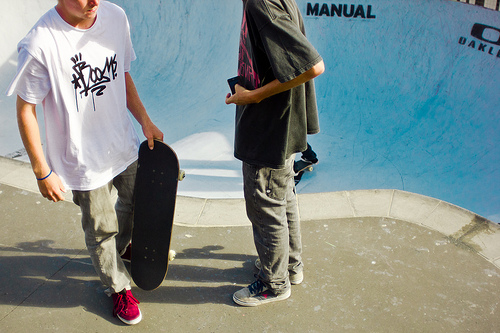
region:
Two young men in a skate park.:
[2, 0, 493, 330]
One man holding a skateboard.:
[9, 0, 187, 325]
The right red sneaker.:
[99, 288, 144, 325]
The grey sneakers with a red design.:
[233, 257, 324, 303]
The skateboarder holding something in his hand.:
[220, 75, 271, 102]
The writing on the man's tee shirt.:
[63, 52, 136, 97]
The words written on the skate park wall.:
[300, 3, 499, 22]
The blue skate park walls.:
[338, 66, 499, 181]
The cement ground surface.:
[316, 241, 483, 331]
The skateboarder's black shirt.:
[226, 1, 330, 159]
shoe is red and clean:
[91, 267, 156, 331]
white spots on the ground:
[354, 220, 412, 273]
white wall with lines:
[330, 188, 392, 230]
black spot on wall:
[448, 196, 488, 265]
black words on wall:
[309, 3, 403, 34]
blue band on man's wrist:
[18, 162, 63, 183]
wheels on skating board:
[168, 156, 194, 183]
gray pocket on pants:
[263, 162, 299, 217]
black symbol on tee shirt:
[61, 49, 141, 124]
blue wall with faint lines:
[345, 52, 492, 156]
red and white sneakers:
[68, 286, 211, 323]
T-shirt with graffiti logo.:
[28, 29, 175, 125]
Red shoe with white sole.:
[90, 281, 194, 323]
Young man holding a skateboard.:
[2, 0, 204, 310]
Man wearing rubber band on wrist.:
[17, 157, 75, 213]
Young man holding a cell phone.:
[195, 42, 349, 139]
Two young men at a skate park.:
[14, 0, 375, 316]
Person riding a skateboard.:
[286, 138, 338, 185]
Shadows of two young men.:
[0, 228, 340, 309]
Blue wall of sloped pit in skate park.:
[297, 0, 499, 223]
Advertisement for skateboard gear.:
[299, 0, 394, 30]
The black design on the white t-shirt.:
[63, 48, 127, 108]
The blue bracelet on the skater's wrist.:
[33, 172, 59, 180]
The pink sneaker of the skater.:
[110, 287, 145, 324]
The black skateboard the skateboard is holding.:
[135, 136, 175, 289]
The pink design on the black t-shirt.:
[236, 16, 264, 101]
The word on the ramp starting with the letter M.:
[301, 0, 376, 27]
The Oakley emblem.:
[458, 15, 499, 42]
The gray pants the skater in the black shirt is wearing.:
[251, 163, 298, 284]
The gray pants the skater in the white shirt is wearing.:
[71, 181, 146, 288]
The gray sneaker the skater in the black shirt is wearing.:
[224, 276, 295, 309]